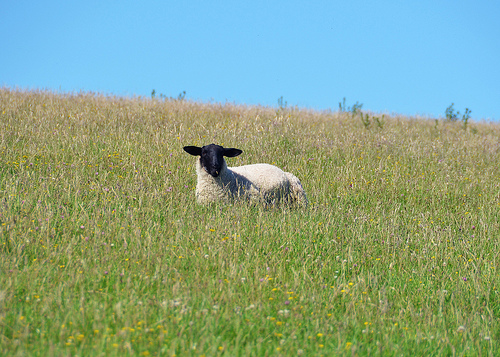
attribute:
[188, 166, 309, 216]
fur — white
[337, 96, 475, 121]
shrubbery — larger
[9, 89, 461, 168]
grass — gold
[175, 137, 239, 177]
face — black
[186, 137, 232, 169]
face — black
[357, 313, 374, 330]
flower — little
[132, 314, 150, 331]
flower — little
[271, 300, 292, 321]
flower — little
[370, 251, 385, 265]
flower — little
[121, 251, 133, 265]
flower — little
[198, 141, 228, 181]
face — black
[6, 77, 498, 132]
weeds — tall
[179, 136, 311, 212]
sheep — white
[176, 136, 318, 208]
sheep — center-photo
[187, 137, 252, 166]
black face — lone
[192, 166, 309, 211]
fur — white, thick, curly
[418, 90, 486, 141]
weeds — tall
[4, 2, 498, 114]
sky — bright, blue, bright blue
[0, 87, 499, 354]
grass — tall, brown and dry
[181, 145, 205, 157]
ear — black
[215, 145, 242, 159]
ear — black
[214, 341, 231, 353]
flower — yellow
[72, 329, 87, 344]
flower — yellow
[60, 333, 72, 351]
flower — yellow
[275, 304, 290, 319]
flower — white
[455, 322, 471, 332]
flower — white